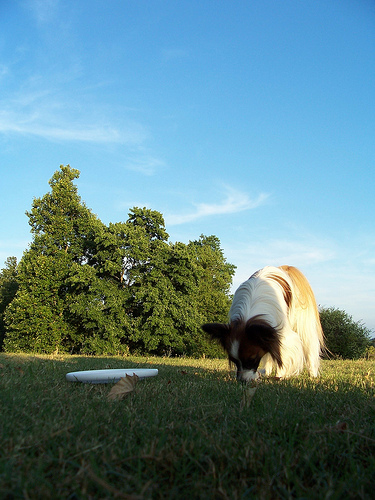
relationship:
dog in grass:
[200, 264, 336, 385] [172, 384, 356, 485]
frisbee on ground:
[66, 368, 159, 383] [0, 343, 373, 495]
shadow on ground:
[83, 377, 363, 496] [186, 375, 248, 433]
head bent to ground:
[200, 316, 286, 386] [89, 385, 363, 487]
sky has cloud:
[148, 102, 357, 209] [156, 184, 272, 231]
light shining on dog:
[255, 264, 325, 378] [197, 264, 327, 382]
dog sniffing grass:
[197, 264, 327, 382] [3, 349, 371, 498]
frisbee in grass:
[66, 368, 159, 383] [3, 349, 371, 498]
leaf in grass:
[108, 376, 140, 408] [136, 387, 278, 460]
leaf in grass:
[106, 372, 139, 407] [165, 380, 315, 440]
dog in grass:
[200, 264, 336, 385] [3, 349, 371, 498]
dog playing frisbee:
[200, 264, 336, 385] [64, 356, 164, 386]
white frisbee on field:
[72, 355, 166, 397] [0, 353, 373, 498]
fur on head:
[201, 310, 282, 370] [198, 310, 291, 388]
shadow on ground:
[8, 347, 374, 497] [0, 343, 373, 495]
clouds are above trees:
[175, 172, 271, 225] [0, 165, 239, 359]